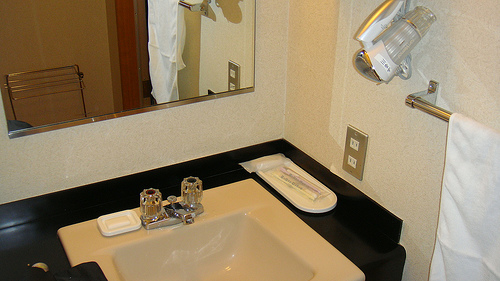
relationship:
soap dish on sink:
[97, 209, 142, 239] [57, 177, 366, 281]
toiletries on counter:
[239, 152, 338, 214] [0, 156, 406, 280]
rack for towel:
[406, 80, 452, 124] [428, 111, 499, 280]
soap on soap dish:
[106, 217, 130, 228] [97, 209, 142, 239]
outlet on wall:
[341, 125, 368, 182] [284, 0, 499, 281]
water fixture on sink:
[140, 178, 204, 231] [57, 177, 366, 281]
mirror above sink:
[0, 1, 258, 139] [57, 177, 366, 281]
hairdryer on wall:
[353, 0, 437, 87] [284, 0, 499, 281]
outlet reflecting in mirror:
[226, 59, 241, 92] [0, 1, 258, 139]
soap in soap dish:
[106, 217, 130, 228] [97, 209, 142, 239]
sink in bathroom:
[57, 177, 366, 281] [2, 1, 499, 280]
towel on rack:
[428, 111, 499, 280] [406, 80, 452, 124]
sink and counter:
[57, 177, 366, 281] [0, 156, 406, 280]